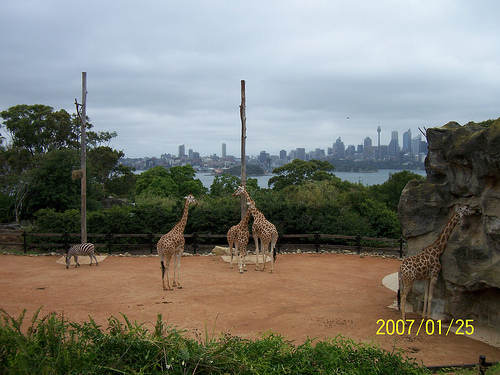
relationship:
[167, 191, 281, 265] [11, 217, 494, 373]
giraffes in enclosure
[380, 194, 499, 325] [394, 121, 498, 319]
giraffe near rock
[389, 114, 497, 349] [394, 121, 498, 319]
face of rock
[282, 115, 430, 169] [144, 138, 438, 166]
skyline of city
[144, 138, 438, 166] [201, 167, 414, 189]
city beyond water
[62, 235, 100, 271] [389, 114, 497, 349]
zebra with face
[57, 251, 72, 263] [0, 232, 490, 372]
face on enclosure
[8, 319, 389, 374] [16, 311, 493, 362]
vegetation in foreground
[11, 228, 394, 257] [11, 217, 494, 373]
fence around enclosure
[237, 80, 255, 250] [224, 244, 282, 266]
pole with food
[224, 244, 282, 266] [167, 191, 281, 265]
food of giraffes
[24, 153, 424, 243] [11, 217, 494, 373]
trees behind enclosure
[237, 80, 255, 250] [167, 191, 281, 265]
pole behind giraffes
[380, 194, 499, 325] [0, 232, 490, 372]
giraffe on enclosure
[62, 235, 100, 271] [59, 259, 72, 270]
zebra has head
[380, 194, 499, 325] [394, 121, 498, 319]
giraffe by rock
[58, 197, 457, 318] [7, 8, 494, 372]
animals in habitat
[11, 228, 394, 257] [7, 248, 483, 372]
fence surrounds area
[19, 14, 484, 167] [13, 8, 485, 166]
smog in air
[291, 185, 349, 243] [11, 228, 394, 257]
shrub by fence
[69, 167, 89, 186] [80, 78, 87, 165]
hay on rope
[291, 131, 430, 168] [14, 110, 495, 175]
skyscrapers on horizon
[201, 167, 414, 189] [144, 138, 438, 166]
water by city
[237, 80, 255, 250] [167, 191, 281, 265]
pole beside giraffes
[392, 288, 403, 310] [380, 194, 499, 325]
tail of giraffe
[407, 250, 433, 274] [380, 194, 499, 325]
spots on giraffe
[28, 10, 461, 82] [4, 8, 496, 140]
clouds in sky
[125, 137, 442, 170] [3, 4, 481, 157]
buildings in background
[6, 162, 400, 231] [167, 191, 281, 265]
plants behind giraffes